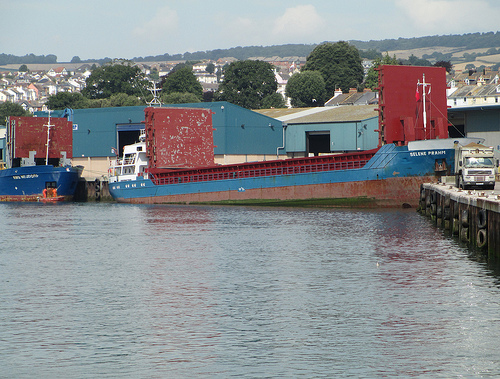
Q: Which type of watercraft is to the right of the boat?
A: The watercraft is a ship.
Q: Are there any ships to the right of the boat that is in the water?
A: Yes, there is a ship to the right of the boat.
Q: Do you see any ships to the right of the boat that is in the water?
A: Yes, there is a ship to the right of the boat.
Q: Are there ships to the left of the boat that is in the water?
A: No, the ship is to the right of the boat.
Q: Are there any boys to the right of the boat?
A: No, there is a ship to the right of the boat.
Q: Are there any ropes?
A: No, there are no ropes.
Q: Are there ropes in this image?
A: No, there are no ropes.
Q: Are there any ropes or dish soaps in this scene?
A: No, there are no ropes or dish soaps.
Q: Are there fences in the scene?
A: No, there are no fences.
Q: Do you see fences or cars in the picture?
A: No, there are no fences or cars.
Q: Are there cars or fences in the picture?
A: No, there are no fences or cars.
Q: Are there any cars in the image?
A: No, there are no cars.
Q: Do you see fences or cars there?
A: No, there are no cars or fences.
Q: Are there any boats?
A: Yes, there is a boat.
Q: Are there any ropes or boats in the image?
A: Yes, there is a boat.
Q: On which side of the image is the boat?
A: The boat is on the left of the image.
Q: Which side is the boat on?
A: The boat is on the left of the image.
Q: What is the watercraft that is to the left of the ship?
A: The watercraft is a boat.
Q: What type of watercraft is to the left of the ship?
A: The watercraft is a boat.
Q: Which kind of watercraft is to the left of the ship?
A: The watercraft is a boat.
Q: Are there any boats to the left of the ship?
A: Yes, there is a boat to the left of the ship.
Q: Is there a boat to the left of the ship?
A: Yes, there is a boat to the left of the ship.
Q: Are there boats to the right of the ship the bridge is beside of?
A: No, the boat is to the left of the ship.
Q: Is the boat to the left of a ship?
A: Yes, the boat is to the left of a ship.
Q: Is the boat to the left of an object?
A: No, the boat is to the left of a ship.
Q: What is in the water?
A: The boat is in the water.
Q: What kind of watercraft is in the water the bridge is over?
A: The watercraft is a boat.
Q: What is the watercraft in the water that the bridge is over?
A: The watercraft is a boat.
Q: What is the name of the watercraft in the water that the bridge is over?
A: The watercraft is a boat.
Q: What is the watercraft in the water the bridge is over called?
A: The watercraft is a boat.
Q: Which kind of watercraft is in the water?
A: The watercraft is a boat.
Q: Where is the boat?
A: The boat is in the water.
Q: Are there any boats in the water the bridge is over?
A: Yes, there is a boat in the water.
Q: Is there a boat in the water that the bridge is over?
A: Yes, there is a boat in the water.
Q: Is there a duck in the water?
A: No, there is a boat in the water.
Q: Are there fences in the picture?
A: No, there are no fences.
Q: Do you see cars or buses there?
A: No, there are no cars or buses.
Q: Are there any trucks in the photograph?
A: Yes, there is a truck.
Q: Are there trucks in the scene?
A: Yes, there is a truck.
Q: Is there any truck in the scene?
A: Yes, there is a truck.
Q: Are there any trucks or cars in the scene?
A: Yes, there is a truck.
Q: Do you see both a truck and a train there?
A: No, there is a truck but no trains.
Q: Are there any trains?
A: No, there are no trains.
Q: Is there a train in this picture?
A: No, there are no trains.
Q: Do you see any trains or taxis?
A: No, there are no trains or taxis.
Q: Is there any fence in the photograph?
A: No, there are no fences.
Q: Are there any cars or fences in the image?
A: No, there are no fences or cars.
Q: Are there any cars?
A: No, there are no cars.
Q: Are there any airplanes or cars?
A: No, there are no cars or airplanes.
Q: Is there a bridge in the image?
A: Yes, there is a bridge.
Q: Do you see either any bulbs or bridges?
A: Yes, there is a bridge.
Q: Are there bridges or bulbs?
A: Yes, there is a bridge.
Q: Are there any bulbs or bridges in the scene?
A: Yes, there is a bridge.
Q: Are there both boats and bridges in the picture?
A: Yes, there are both a bridge and a boat.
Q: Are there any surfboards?
A: No, there are no surfboards.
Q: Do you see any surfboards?
A: No, there are no surfboards.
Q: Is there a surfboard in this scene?
A: No, there are no surfboards.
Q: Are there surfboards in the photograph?
A: No, there are no surfboards.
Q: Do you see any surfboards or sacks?
A: No, there are no surfboards or sacks.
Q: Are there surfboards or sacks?
A: No, there are no surfboards or sacks.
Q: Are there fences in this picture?
A: No, there are no fences.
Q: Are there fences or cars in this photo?
A: No, there are no fences or cars.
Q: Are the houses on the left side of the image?
A: Yes, the houses are on the left of the image.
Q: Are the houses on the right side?
A: No, the houses are on the left of the image.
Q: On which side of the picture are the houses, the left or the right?
A: The houses are on the left of the image.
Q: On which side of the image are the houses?
A: The houses are on the left of the image.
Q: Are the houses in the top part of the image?
A: Yes, the houses are in the top of the image.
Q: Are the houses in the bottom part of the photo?
A: No, the houses are in the top of the image.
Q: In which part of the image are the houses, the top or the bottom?
A: The houses are in the top of the image.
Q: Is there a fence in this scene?
A: No, there are no fences.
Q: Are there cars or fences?
A: No, there are no fences or cars.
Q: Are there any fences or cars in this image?
A: No, there are no fences or cars.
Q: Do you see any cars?
A: No, there are no cars.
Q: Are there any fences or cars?
A: No, there are no cars or fences.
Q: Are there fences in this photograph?
A: No, there are no fences.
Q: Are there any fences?
A: No, there are no fences.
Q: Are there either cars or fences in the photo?
A: No, there are no fences or cars.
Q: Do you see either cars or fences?
A: No, there are no fences or cars.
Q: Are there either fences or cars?
A: No, there are no cars or fences.